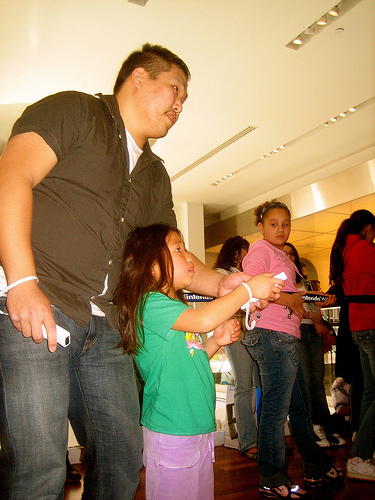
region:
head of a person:
[100, 37, 201, 129]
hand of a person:
[4, 266, 60, 339]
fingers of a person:
[6, 315, 57, 343]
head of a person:
[132, 215, 220, 293]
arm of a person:
[163, 277, 253, 341]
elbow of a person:
[198, 303, 213, 333]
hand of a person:
[209, 322, 245, 347]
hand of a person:
[246, 256, 277, 298]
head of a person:
[253, 193, 297, 249]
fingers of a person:
[259, 270, 280, 303]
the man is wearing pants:
[81, 371, 142, 497]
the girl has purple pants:
[142, 433, 207, 498]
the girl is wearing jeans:
[253, 338, 293, 440]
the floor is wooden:
[221, 457, 244, 492]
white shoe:
[350, 454, 374, 478]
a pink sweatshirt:
[256, 248, 284, 269]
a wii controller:
[59, 324, 76, 348]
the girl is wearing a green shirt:
[143, 341, 208, 430]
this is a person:
[241, 194, 306, 496]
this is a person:
[108, 211, 226, 496]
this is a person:
[1, 37, 204, 498]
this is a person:
[210, 222, 271, 459]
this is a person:
[329, 210, 372, 482]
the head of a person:
[98, 26, 200, 142]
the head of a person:
[127, 217, 209, 300]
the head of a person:
[215, 227, 262, 288]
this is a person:
[189, 193, 312, 498]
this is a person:
[121, 221, 251, 494]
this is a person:
[202, 216, 275, 468]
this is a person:
[279, 228, 343, 494]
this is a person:
[11, 25, 197, 496]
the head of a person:
[106, 39, 197, 145]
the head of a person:
[114, 205, 201, 303]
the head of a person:
[217, 222, 266, 273]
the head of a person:
[252, 186, 315, 252]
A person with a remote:
[119, 231, 260, 491]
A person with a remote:
[19, 11, 182, 498]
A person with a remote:
[251, 210, 322, 497]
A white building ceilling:
[271, 58, 363, 139]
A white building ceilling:
[201, 120, 290, 197]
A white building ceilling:
[183, 1, 268, 70]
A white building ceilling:
[7, 1, 86, 57]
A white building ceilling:
[302, 135, 338, 189]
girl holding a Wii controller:
[221, 265, 293, 319]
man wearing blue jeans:
[2, 288, 151, 489]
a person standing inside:
[237, 187, 308, 398]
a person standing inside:
[101, 211, 277, 498]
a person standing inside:
[18, 52, 203, 445]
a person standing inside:
[331, 197, 373, 282]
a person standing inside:
[196, 215, 253, 345]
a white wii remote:
[45, 317, 85, 368]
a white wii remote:
[214, 248, 292, 344]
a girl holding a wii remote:
[151, 258, 306, 338]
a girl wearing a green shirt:
[109, 218, 295, 497]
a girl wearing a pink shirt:
[233, 196, 333, 498]